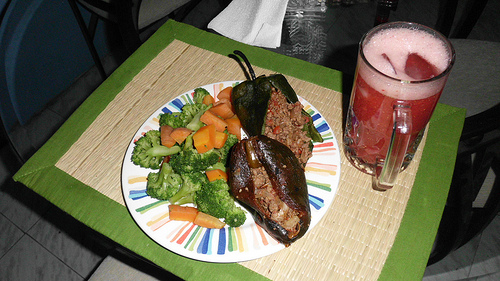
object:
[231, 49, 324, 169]
pepper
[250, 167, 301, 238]
meat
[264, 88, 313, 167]
meat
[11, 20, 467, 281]
mat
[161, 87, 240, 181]
piece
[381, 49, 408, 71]
ice cubes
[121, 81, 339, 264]
plate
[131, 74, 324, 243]
supper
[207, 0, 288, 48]
towel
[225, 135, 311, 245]
pepper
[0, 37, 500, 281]
ground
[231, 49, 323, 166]
stuffed pepper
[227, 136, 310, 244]
stuffed pepper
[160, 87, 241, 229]
carrot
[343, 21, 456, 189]
glass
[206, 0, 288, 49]
napkin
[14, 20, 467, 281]
table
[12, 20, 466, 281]
placemat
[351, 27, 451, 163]
drink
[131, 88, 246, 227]
broccoli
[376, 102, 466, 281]
border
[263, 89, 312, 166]
rice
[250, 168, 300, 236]
rice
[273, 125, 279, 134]
tomato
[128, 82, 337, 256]
stripes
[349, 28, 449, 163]
pop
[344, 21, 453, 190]
mug